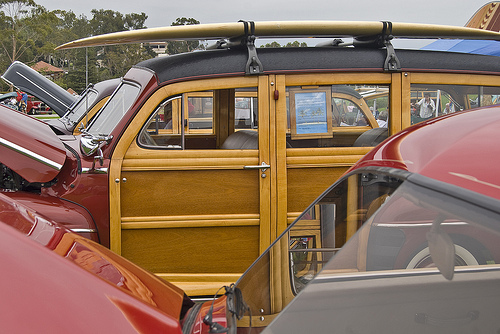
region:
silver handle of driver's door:
[244, 155, 269, 176]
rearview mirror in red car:
[410, 207, 477, 268]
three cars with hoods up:
[2, 10, 487, 325]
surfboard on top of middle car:
[53, 19, 498, 41]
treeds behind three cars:
[7, 4, 237, 83]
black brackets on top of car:
[217, 9, 394, 69]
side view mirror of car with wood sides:
[69, 120, 113, 160]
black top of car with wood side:
[150, 45, 490, 73]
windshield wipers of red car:
[211, 285, 246, 332]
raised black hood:
[1, 49, 76, 112]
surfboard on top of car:
[42, 23, 498, 48]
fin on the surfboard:
[463, 5, 497, 27]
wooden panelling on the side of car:
[122, 63, 497, 283]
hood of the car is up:
[9, 213, 187, 332]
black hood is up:
[2, 42, 89, 113]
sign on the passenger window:
[291, 78, 349, 145]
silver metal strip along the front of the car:
[4, 132, 115, 172]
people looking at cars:
[13, 85, 37, 117]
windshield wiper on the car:
[209, 281, 259, 332]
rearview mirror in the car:
[417, 201, 467, 290]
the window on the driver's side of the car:
[136, 84, 260, 151]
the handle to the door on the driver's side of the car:
[243, 163, 269, 169]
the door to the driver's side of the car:
[111, 74, 271, 298]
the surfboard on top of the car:
[51, 20, 499, 51]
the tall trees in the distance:
[0, 0, 307, 90]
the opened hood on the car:
[0, 98, 66, 180]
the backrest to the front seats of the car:
[218, 128, 256, 150]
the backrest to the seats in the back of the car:
[352, 125, 387, 143]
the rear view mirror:
[425, 212, 453, 277]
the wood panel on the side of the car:
[108, 73, 498, 295]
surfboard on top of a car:
[73, 17, 485, 67]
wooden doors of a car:
[113, 105, 297, 260]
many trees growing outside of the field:
[3, 8, 143, 63]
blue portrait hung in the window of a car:
[274, 86, 337, 148]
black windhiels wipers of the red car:
[192, 284, 242, 332]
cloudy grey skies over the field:
[171, 0, 369, 21]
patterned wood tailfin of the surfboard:
[458, 5, 498, 35]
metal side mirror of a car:
[66, 129, 118, 171]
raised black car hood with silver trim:
[6, 64, 81, 111]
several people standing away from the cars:
[0, 81, 56, 113]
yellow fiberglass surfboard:
[45, 14, 490, 49]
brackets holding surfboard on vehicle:
[230, 18, 407, 93]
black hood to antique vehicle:
[4, 53, 84, 115]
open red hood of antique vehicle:
[1, 88, 82, 198]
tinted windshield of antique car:
[164, 129, 499, 331]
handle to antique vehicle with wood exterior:
[210, 125, 285, 202]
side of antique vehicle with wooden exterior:
[2, 68, 498, 322]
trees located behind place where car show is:
[0, 0, 332, 201]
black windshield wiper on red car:
[167, 256, 279, 331]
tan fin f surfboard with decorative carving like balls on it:
[401, 0, 498, 54]